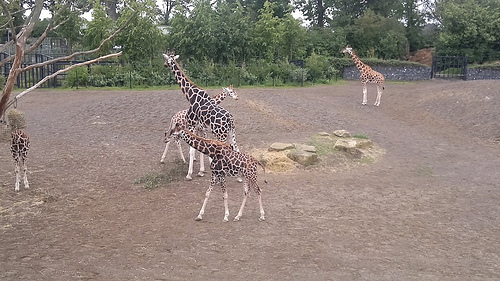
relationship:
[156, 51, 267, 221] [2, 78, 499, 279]
giraffes on ground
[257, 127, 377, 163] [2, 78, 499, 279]
rocks on ground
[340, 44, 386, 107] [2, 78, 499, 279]
giraffe on ground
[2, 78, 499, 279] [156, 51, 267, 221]
ground under giraffes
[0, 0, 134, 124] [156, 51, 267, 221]
tree by giraffes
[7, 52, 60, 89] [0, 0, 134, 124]
gate behind tree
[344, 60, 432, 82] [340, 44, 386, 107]
wall behind giraffe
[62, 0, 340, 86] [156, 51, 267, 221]
trees behind giraffes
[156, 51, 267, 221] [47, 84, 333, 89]
giraffes by grass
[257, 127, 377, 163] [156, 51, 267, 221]
rocks near giraffes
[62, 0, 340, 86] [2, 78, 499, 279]
trees above ground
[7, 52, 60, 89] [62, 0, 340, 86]
gate near trees